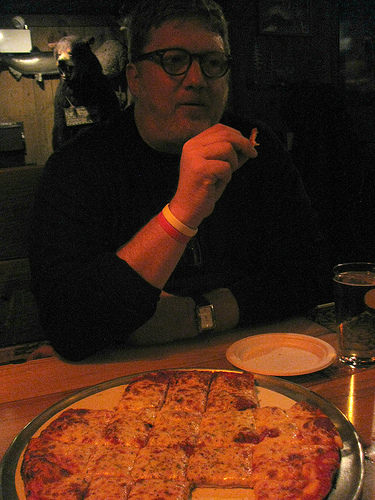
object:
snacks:
[20, 366, 340, 500]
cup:
[331, 262, 374, 367]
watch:
[190, 292, 216, 337]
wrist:
[186, 296, 207, 337]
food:
[249, 128, 260, 148]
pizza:
[20, 368, 342, 500]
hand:
[177, 122, 258, 214]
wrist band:
[158, 204, 198, 244]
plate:
[224, 331, 334, 379]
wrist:
[155, 197, 199, 255]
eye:
[165, 55, 184, 65]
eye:
[206, 58, 221, 68]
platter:
[0, 365, 365, 500]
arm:
[192, 137, 331, 339]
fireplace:
[158, 203, 198, 243]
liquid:
[332, 269, 375, 359]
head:
[124, 0, 233, 148]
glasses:
[132, 47, 234, 78]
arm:
[32, 157, 194, 362]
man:
[28, 0, 326, 362]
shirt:
[31, 102, 326, 365]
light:
[346, 370, 356, 425]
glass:
[331, 258, 373, 370]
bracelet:
[156, 202, 198, 248]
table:
[0, 314, 375, 497]